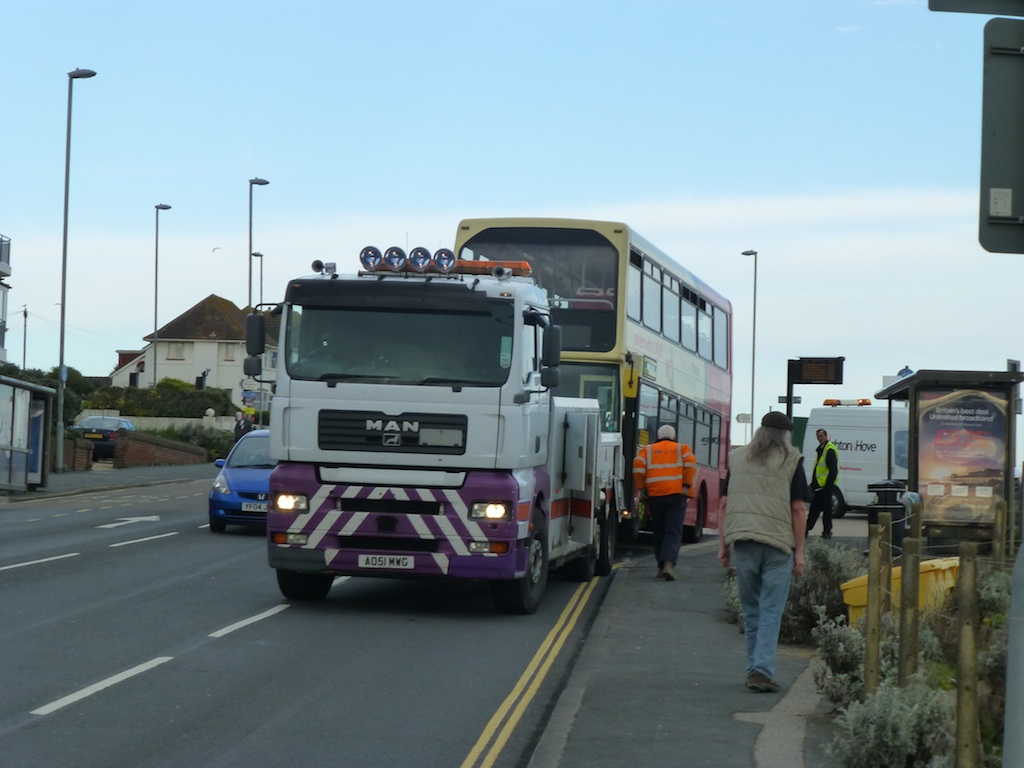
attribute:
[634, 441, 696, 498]
jacket — orange 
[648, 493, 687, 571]
pants — blue 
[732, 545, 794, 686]
jeans — blue 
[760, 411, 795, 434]
cap — black 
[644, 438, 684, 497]
vest — orange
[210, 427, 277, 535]
car — blue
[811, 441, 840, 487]
vest — yellow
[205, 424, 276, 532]
car — blue